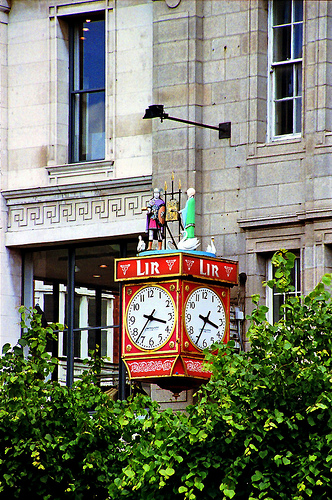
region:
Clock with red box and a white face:
[107, 239, 250, 396]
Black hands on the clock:
[129, 296, 160, 336]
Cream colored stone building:
[22, 54, 128, 242]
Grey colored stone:
[166, 70, 252, 163]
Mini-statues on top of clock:
[126, 170, 220, 254]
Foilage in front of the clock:
[2, 390, 318, 488]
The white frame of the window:
[242, 238, 307, 353]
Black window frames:
[10, 243, 124, 388]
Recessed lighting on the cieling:
[70, 250, 115, 286]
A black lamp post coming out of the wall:
[130, 86, 249, 152]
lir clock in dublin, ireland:
[91, 161, 260, 420]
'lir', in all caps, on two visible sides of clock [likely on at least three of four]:
[132, 259, 219, 278]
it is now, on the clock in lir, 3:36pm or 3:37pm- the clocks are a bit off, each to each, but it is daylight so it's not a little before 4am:
[123, 280, 229, 360]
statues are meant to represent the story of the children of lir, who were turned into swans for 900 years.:
[142, 184, 198, 251]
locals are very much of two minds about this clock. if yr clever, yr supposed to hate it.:
[106, 165, 250, 424]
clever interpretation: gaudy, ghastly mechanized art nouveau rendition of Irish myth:
[110, 170, 244, 387]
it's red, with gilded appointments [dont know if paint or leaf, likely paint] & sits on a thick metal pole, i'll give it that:
[112, 252, 238, 382]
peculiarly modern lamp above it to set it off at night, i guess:
[136, 97, 236, 147]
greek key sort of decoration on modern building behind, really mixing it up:
[2, 190, 152, 230]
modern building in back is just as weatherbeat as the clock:
[3, 59, 331, 409]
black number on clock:
[142, 285, 152, 303]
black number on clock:
[146, 336, 155, 346]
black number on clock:
[161, 323, 170, 331]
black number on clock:
[164, 309, 174, 320]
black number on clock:
[124, 314, 137, 323]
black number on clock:
[168, 312, 171, 321]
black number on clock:
[130, 304, 139, 312]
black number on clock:
[185, 301, 198, 311]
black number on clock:
[186, 326, 196, 333]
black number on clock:
[207, 336, 213, 343]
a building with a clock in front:
[42, 138, 297, 373]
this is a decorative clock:
[95, 166, 263, 390]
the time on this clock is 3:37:
[100, 247, 275, 397]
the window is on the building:
[38, 2, 130, 192]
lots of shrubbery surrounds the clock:
[22, 307, 303, 441]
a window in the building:
[10, 234, 135, 407]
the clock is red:
[106, 245, 258, 398]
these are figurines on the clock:
[124, 171, 236, 259]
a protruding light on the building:
[125, 65, 244, 167]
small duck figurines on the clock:
[134, 227, 222, 255]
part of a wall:
[293, 166, 314, 189]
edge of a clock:
[177, 294, 188, 345]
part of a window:
[296, 93, 302, 111]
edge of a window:
[64, 102, 91, 149]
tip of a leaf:
[231, 452, 257, 474]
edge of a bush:
[256, 442, 271, 459]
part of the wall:
[163, 392, 170, 410]